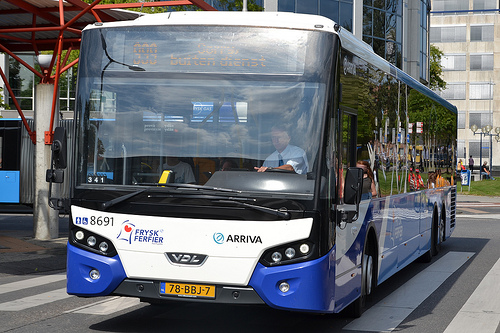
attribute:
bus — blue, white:
[66, 11, 457, 315]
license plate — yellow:
[158, 281, 216, 298]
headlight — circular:
[89, 269, 100, 279]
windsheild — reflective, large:
[73, 27, 340, 205]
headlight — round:
[280, 281, 288, 291]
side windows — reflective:
[338, 47, 457, 199]